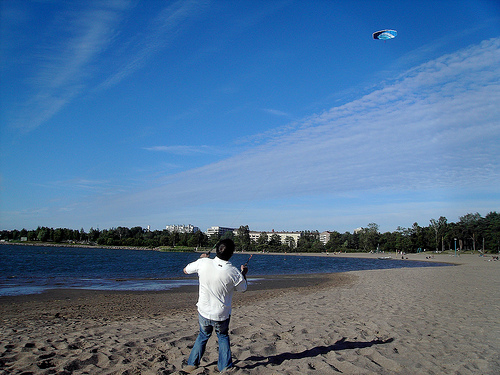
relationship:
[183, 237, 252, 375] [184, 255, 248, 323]
person wearing shirt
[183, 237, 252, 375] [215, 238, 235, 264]
person has hair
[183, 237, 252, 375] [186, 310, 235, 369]
person wearing jeans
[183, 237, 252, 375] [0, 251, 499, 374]
person standing in sand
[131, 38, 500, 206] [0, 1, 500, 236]
clouds in sky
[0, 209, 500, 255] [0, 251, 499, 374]
trees near sand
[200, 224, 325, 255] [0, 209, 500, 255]
building beyond trees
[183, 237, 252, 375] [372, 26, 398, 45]
person flying kite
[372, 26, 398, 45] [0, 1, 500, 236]
kite in sky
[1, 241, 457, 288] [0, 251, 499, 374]
water on sand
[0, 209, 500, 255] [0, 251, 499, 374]
trees lining sand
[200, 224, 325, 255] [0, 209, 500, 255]
building behind trees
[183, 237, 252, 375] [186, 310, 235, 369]
person in jeans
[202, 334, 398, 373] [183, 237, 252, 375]
shadow of person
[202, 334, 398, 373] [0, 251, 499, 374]
shadow on sand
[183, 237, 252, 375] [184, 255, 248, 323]
person in shirt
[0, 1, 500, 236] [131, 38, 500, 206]
sky with clouds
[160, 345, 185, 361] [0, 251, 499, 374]
footstep in sand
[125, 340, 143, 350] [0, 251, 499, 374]
footstep in sand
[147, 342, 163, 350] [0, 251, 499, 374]
footstep in sand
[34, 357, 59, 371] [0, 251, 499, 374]
footstep in sand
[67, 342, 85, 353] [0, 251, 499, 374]
footstep in sand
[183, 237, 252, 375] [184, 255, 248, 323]
person with shirt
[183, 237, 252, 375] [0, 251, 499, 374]
person standing on sand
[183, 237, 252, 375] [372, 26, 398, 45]
person watching kite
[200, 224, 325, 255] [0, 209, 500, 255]
building by trees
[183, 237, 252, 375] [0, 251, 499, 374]
person on sand